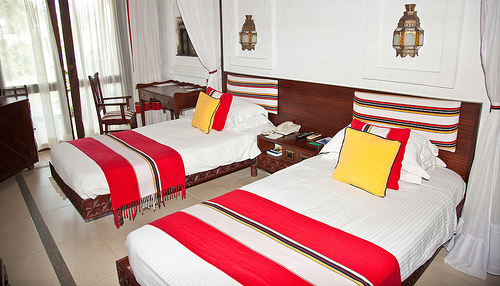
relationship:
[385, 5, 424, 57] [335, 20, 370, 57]
light on wall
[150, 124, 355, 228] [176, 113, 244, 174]
twin size bed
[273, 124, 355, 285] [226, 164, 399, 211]
twin sized bed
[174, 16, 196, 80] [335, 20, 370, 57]
art on wall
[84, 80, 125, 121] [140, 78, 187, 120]
chair by desk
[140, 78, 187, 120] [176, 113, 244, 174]
desk by bed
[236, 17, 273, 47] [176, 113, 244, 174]
light above bed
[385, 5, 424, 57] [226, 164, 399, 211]
light by bed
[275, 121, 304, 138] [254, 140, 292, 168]
phone on table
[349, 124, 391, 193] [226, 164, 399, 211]
pillow on bed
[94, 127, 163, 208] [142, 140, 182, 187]
blanket has red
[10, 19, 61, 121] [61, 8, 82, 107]
curtains at window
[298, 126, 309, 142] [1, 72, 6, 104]
remote for tv